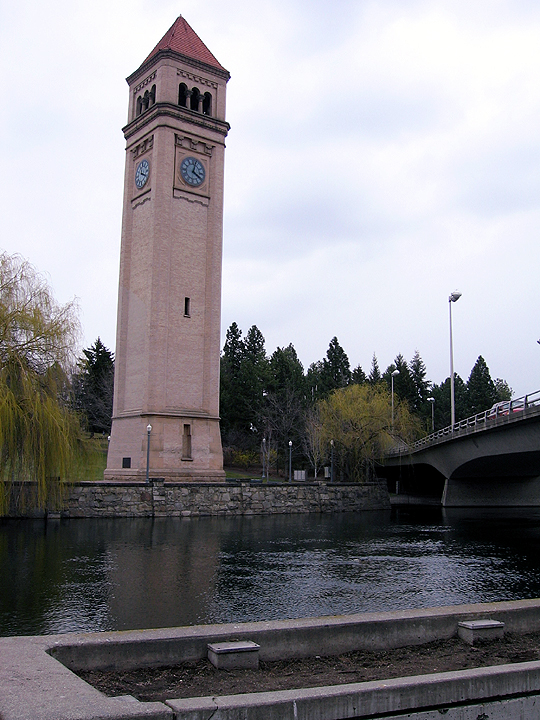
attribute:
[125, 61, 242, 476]
tower — pink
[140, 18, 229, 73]
roof — red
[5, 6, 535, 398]
sky — blue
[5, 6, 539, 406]
clouds — white